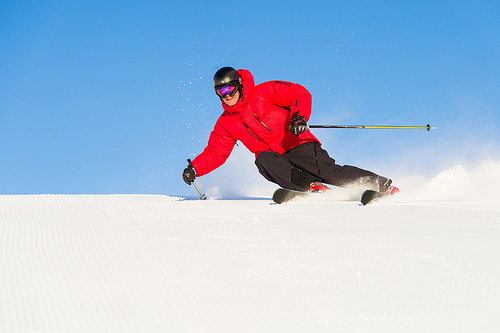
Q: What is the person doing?
A: Skiing.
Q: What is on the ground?
A: Snow.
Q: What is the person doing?
A: Skiing.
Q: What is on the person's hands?
A: Gloves.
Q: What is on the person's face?
A: Goggles.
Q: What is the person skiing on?
A: Snow.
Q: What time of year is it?
A: Winter.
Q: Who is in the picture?
A: A skier.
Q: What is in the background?
A: The sky.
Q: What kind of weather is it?
A: A clear day.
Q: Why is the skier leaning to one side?
A: He is turning.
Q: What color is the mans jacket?
A: Red.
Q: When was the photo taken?
A: Daytime.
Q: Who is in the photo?
A: A man.